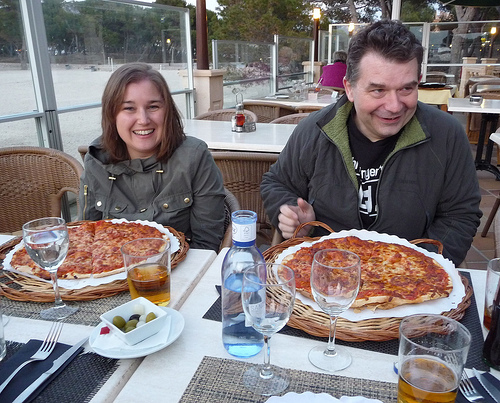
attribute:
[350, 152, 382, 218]
design — white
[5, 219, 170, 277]
pizza — large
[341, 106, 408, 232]
shirt — white, black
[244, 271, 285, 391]
glass — clear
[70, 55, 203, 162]
hair — brown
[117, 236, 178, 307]
glass — half-full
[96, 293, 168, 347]
dish — white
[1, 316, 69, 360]
fork — silver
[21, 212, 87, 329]
water — clear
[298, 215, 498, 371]
pizza — large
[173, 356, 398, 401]
placemat — light brown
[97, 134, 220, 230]
jacket — grey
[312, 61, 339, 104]
jacket — purple